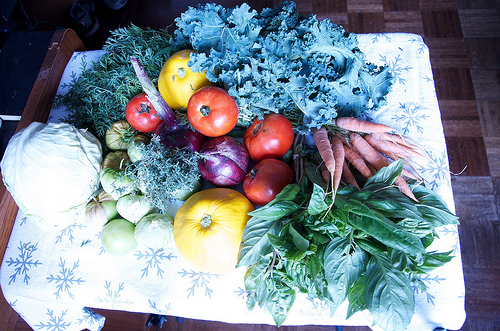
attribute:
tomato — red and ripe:
[194, 116, 298, 153]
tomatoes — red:
[185, 90, 290, 151]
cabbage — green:
[2, 120, 112, 230]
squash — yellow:
[171, 185, 269, 277]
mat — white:
[19, 38, 465, 308]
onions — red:
[166, 136, 250, 185]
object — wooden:
[8, 28, 61, 128]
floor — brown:
[452, 46, 498, 152]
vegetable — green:
[127, 54, 190, 134]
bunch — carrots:
[305, 111, 429, 201]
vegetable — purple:
[203, 133, 253, 182]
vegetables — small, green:
[81, 33, 437, 308]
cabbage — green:
[0, 117, 115, 218]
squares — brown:
[438, 21, 496, 117]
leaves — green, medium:
[326, 205, 433, 285]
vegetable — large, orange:
[160, 50, 210, 110]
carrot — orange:
[333, 112, 398, 133]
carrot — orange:
[313, 120, 337, 188]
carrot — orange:
[327, 129, 346, 220]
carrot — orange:
[343, 148, 371, 179]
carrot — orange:
[343, 131, 420, 201]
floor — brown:
[53, 0, 499, 331]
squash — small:
[173, 180, 251, 273]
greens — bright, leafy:
[63, 6, 461, 329]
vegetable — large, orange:
[171, 185, 254, 270]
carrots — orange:
[314, 111, 427, 210]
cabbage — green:
[0, 118, 107, 223]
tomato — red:
[240, 150, 291, 197]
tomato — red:
[245, 109, 291, 163]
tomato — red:
[186, 84, 239, 134]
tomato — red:
[127, 90, 158, 134]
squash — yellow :
[173, 183, 245, 277]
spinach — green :
[238, 191, 446, 315]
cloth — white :
[11, 251, 141, 313]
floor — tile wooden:
[460, 110, 482, 160]